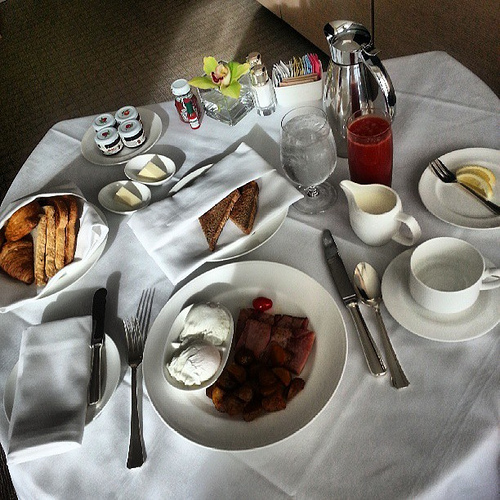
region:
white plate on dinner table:
[139, 266, 334, 434]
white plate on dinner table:
[19, 321, 130, 420]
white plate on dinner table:
[114, 183, 312, 253]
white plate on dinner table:
[431, 164, 498, 245]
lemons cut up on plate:
[457, 166, 497, 193]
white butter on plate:
[177, 301, 237, 404]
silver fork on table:
[142, 288, 152, 498]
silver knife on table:
[311, 238, 394, 379]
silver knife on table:
[69, 295, 119, 406]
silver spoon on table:
[334, 239, 436, 442]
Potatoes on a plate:
[208, 359, 313, 420]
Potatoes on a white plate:
[202, 345, 314, 421]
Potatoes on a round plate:
[205, 346, 303, 420]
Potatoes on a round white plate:
[203, 345, 311, 421]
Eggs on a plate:
[169, 297, 231, 387]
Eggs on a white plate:
[170, 298, 234, 383]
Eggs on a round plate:
[165, 297, 231, 383]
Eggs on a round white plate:
[166, 296, 231, 386]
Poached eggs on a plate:
[165, 297, 230, 384]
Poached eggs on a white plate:
[162, 297, 232, 386]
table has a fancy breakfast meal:
[1, 20, 498, 499]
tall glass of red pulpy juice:
[346, 106, 392, 188]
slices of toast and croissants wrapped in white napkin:
[1, 184, 108, 313]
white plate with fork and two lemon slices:
[418, 146, 498, 228]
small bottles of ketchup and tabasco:
[170, 77, 199, 127]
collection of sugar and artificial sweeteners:
[272, 53, 322, 85]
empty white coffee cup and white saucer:
[379, 235, 499, 342]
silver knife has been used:
[321, 229, 386, 376]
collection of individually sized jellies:
[81, 105, 162, 163]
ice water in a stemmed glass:
[280, 105, 338, 214]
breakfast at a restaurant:
[5, 30, 494, 492]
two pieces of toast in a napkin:
[178, 152, 278, 269]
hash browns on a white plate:
[217, 351, 298, 431]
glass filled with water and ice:
[285, 108, 340, 215]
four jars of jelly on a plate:
[80, 91, 162, 163]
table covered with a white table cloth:
[15, 85, 490, 497]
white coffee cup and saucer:
[389, 238, 499, 347]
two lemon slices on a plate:
[456, 156, 495, 205]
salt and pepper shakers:
[247, 47, 277, 119]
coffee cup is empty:
[405, 230, 495, 304]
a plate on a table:
[143, 257, 380, 422]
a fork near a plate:
[101, 261, 212, 468]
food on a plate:
[136, 270, 335, 454]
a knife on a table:
[324, 212, 385, 392]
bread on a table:
[187, 135, 300, 269]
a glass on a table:
[275, 79, 397, 209]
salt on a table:
[237, 58, 304, 130]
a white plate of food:
[126, 180, 422, 472]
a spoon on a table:
[351, 231, 417, 385]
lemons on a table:
[446, 148, 498, 199]